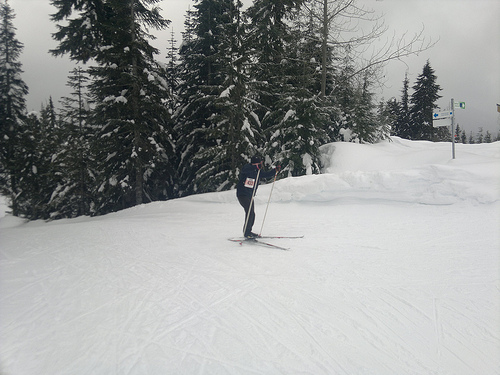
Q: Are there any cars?
A: No, there are no cars.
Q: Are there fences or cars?
A: No, there are no cars or fences.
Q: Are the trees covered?
A: Yes, the trees are covered.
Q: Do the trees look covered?
A: Yes, the trees are covered.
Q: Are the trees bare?
A: No, the trees are covered.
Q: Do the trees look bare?
A: No, the trees are covered.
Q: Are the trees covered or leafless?
A: The trees are covered.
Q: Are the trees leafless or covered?
A: The trees are covered.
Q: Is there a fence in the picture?
A: No, there are no fences.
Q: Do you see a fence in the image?
A: No, there are no fences.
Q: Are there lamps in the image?
A: No, there are no lamps.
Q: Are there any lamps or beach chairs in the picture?
A: No, there are no lamps or beach chairs.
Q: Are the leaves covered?
A: Yes, the leaves are covered.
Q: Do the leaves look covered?
A: Yes, the leaves are covered.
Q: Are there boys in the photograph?
A: No, there are no boys.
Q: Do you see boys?
A: No, there are no boys.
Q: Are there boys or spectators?
A: No, there are no boys or spectators.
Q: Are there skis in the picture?
A: Yes, there are skis.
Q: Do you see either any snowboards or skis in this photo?
A: Yes, there are skis.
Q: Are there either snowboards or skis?
A: Yes, there are skis.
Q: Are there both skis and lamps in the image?
A: No, there are skis but no lamps.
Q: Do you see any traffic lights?
A: No, there are no traffic lights.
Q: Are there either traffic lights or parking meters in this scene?
A: No, there are no traffic lights or parking meters.